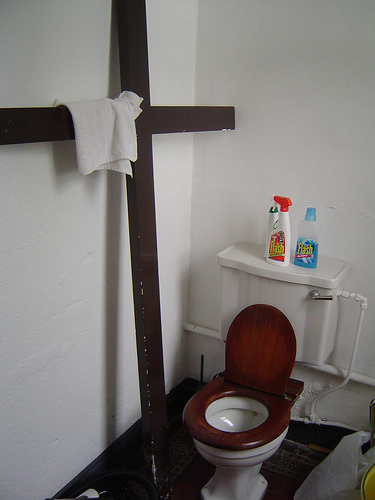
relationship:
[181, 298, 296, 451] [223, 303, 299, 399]
seat made out of lid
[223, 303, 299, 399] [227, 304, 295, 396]
lid made out of wood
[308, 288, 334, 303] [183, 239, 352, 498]
flusher on toilet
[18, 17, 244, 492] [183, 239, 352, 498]
cross by a toilet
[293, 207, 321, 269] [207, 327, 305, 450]
cleaning product are on toilet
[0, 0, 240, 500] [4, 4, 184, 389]
cross on wall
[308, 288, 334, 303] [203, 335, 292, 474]
flusher on a toilet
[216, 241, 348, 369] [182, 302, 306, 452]
toilet with seat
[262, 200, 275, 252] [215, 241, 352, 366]
cleaning product on top of toilet tank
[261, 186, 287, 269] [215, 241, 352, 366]
cleaning product on top of toilet tank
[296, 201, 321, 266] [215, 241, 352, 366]
cleaning product on top of toilet tank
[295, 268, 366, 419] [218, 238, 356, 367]
pipe coming out of toilet tank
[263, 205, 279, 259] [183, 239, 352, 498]
cleaning product on toilet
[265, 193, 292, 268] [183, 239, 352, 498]
cleaning product on toilet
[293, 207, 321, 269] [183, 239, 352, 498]
cleaning product on toilet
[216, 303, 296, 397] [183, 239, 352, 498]
lid on toilet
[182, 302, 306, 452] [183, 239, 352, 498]
seat on toilet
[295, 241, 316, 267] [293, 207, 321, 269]
liquid in cleaning product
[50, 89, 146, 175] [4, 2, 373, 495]
towel in photo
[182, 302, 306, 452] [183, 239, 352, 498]
seat in toilet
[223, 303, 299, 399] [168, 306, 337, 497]
lid on toilet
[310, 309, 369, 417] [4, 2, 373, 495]
pipe in photo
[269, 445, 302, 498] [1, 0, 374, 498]
carpet in bathroom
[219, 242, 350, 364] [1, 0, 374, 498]
toilet tank in bathroom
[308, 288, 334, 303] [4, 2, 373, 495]
flusher in photo